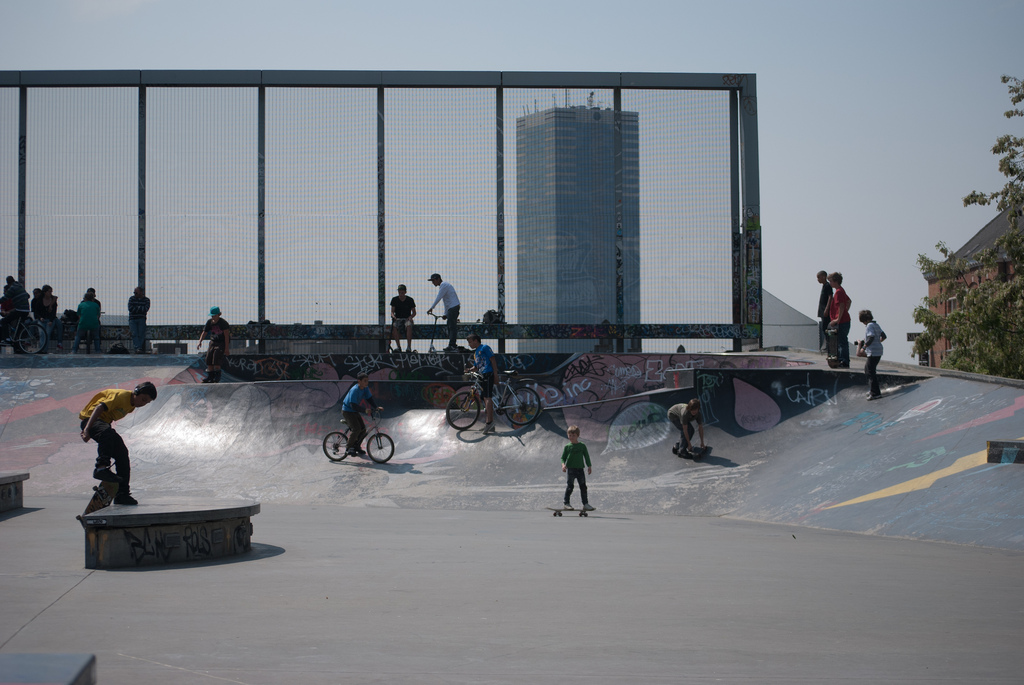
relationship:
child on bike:
[341, 373, 384, 455] [319, 395, 402, 469]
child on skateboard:
[667, 398, 706, 459] [662, 424, 719, 472]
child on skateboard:
[667, 398, 706, 459] [658, 430, 730, 472]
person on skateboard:
[64, 357, 183, 511] [77, 462, 132, 542]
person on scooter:
[423, 266, 482, 362] [408, 296, 489, 389]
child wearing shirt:
[332, 370, 382, 425] [349, 366, 373, 425]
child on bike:
[332, 370, 382, 425] [304, 403, 398, 462]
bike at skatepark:
[443, 365, 543, 432] [5, 8, 1017, 681]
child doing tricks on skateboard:
[664, 389, 710, 457] [669, 435, 721, 466]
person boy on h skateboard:
[79, 381, 157, 505] [60, 481, 154, 518]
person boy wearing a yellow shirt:
[79, 381, 157, 505] [84, 373, 126, 425]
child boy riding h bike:
[341, 373, 384, 455] [322, 436, 398, 469]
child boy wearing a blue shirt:
[341, 373, 384, 455] [343, 378, 365, 418]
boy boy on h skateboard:
[561, 424, 594, 510] [549, 499, 588, 532]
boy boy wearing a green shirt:
[561, 424, 594, 510] [557, 445, 583, 458]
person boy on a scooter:
[427, 273, 461, 351] [432, 317, 463, 344]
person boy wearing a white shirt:
[427, 273, 461, 351] [436, 287, 456, 354]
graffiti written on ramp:
[706, 364, 1020, 520] [929, 473, 996, 549]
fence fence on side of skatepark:
[0, 70, 764, 355] [0, 315, 973, 685]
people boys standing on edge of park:
[817, 270, 852, 367] [750, 356, 1014, 421]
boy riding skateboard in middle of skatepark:
[523, 414, 604, 598] [58, 295, 992, 685]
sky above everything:
[20, 110, 1012, 342] [13, 207, 1009, 277]